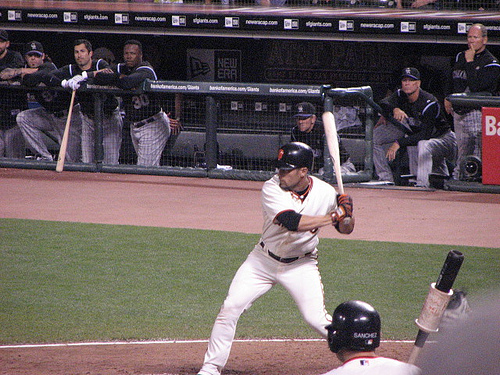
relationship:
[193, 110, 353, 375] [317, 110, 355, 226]
baseball player holding baseball bat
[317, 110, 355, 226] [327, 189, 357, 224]
baseball bat in hands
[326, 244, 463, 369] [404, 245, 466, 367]
baseball player holding bat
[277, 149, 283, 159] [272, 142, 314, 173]
ornament on helmet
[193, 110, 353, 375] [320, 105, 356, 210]
baseball player with bat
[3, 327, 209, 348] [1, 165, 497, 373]
line on field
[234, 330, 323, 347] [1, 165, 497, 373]
line on field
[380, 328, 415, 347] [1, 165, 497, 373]
line on field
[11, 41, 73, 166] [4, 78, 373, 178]
player leaning over railing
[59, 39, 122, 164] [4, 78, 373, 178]
player leaning over railing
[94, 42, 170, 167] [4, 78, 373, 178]
player leaning over railing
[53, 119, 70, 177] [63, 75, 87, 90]
bat in hands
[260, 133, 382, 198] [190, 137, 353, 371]
helmet on man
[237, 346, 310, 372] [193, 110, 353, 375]
dirt beneath baseball player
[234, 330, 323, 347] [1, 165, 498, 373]
line on ground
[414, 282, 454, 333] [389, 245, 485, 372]
weight trainer on bat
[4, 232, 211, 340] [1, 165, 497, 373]
grass on field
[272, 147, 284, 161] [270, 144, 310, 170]
logo on helmet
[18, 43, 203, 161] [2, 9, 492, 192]
team in dugout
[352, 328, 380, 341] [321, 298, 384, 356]
sanchez on helmet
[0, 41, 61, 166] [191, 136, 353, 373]
player watching batter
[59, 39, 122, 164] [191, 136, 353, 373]
player watching batter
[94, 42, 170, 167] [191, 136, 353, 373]
player watching batter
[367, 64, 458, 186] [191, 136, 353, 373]
team member watching batter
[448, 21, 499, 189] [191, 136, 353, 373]
team member watching batter